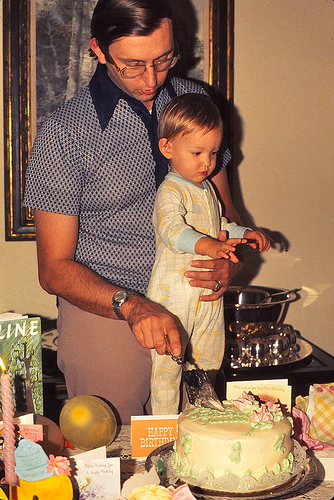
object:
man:
[21, 0, 243, 425]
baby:
[144, 93, 271, 416]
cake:
[175, 390, 297, 491]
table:
[14, 410, 333, 499]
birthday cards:
[129, 412, 180, 464]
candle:
[0, 358, 18, 500]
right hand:
[126, 298, 181, 361]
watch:
[110, 288, 130, 320]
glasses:
[105, 45, 182, 79]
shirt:
[21, 76, 233, 297]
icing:
[198, 402, 238, 425]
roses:
[237, 391, 282, 423]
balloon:
[57, 393, 118, 453]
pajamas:
[144, 172, 251, 415]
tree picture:
[40, 1, 83, 119]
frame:
[4, 0, 236, 246]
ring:
[213, 279, 222, 292]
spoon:
[255, 287, 303, 304]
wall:
[1, 0, 333, 344]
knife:
[165, 342, 222, 413]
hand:
[183, 255, 241, 303]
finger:
[187, 279, 223, 291]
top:
[188, 391, 288, 436]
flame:
[0, 353, 7, 370]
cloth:
[292, 380, 333, 442]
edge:
[141, 470, 319, 499]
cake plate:
[144, 437, 319, 499]